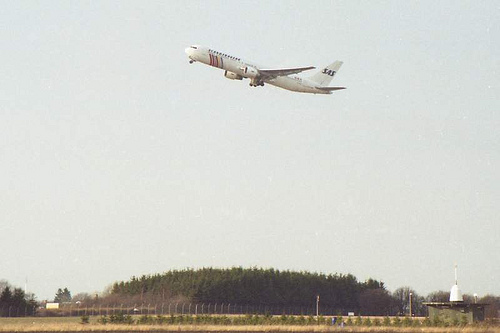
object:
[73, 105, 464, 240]
gray sky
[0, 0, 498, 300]
clouds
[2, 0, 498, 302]
sky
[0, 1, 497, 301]
overcast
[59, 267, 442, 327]
fence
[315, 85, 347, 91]
wing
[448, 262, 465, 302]
white top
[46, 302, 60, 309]
building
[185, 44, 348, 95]
airplane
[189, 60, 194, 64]
wheel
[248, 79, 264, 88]
landing gear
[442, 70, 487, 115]
ground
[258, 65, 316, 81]
wing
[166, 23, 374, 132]
jet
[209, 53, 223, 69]
stripe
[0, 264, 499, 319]
trees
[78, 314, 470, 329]
bushes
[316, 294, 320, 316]
light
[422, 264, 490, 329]
building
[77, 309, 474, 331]
trees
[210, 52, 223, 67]
stripes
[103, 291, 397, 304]
airport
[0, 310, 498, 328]
runway